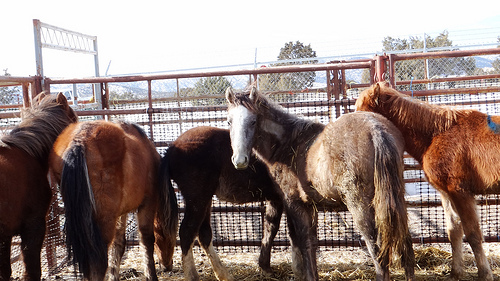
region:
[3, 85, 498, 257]
A group of horses standing together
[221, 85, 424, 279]
A horse looking backwards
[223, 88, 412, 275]
A brown horse with white face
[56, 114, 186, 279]
A horse eating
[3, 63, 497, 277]
Horses in front of a fence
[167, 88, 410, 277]
Horse standing in front of another horse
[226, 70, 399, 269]
Horse standing in front of fence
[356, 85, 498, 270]
Horse with blue mark on it's back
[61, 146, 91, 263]
Tail of a horse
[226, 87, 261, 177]
Horse with a white nose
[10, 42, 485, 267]
The horses are in an enclosure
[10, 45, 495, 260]
Some horses are in a corral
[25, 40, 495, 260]
The horses are at a rodeo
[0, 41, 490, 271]
The horses are behind a fence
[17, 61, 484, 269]
The horses are male and female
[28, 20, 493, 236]
The horses are eating some hay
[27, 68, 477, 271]
The horses are getting along well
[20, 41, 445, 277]
The horses are out in the sunshine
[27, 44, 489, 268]
The horses are enjoying the day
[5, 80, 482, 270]
horses in the enclosure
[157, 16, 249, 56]
the sky is bright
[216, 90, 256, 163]
front of the horse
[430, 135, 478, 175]
the horse is brown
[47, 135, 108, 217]
tail of the horse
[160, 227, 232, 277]
legs of the horse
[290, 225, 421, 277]
legs of the horse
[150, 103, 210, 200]
back of the horse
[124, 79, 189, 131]
fence of the enclosure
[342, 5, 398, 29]
the sky is clear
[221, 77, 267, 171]
the head of a horse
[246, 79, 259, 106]
the ear of a horse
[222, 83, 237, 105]
the ear of a horse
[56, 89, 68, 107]
the ear of a horse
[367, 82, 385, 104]
the ear of a horse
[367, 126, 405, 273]
the tail of a horse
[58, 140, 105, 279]
the tail of a horse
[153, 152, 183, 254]
the tail of a horse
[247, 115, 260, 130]
the eye of a horse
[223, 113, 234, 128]
the eye of a horse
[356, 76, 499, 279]
brown horse with a blue print on its back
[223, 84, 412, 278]
brown horse with a white face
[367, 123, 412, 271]
brown tail of horse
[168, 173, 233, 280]
brown and white horse legs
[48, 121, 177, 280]
brown horse with a black tail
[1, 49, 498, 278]
horses in a stable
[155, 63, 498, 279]
three horses standing on hay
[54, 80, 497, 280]
four horses standing on hay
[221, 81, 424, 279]
white face brown horse standing on hay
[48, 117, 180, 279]
brown horse with a black tail eating